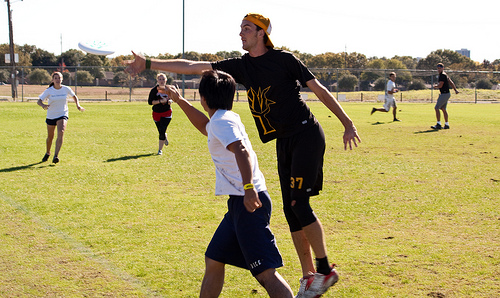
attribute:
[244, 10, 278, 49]
hat — orange, yellow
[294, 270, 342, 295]
shoe — red, white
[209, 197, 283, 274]
shorts — blue, black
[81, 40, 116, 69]
frisbee — white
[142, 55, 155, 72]
ankle brace — black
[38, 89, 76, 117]
shirt — white, dark, red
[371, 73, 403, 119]
man — running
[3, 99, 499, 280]
grass — green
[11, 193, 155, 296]
line — white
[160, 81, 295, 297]
girl — running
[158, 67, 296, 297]
boy — playing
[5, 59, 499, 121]
fence — chain linked, grey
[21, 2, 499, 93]
sky — bright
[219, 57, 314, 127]
shirt — black